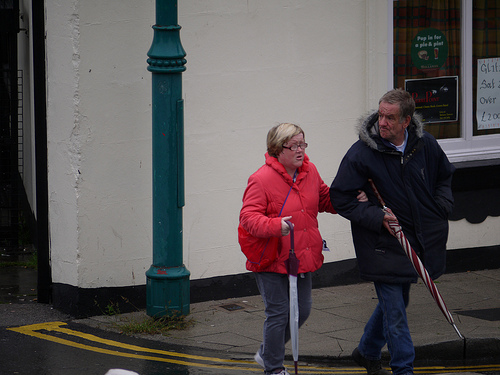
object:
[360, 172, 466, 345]
umbrella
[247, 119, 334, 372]
woman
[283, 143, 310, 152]
glasses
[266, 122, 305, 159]
hair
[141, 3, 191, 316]
post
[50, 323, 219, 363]
lines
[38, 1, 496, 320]
building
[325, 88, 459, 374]
man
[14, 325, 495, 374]
street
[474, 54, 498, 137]
sign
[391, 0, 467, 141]
window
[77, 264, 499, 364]
sidewalk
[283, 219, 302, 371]
umbrella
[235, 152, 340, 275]
jacket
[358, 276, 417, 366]
jeans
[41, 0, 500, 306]
wall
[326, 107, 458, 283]
jacket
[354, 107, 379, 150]
hood